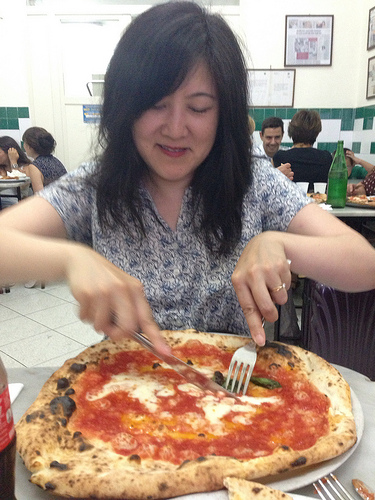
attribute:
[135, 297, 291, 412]
fork — silver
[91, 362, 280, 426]
cheese — white